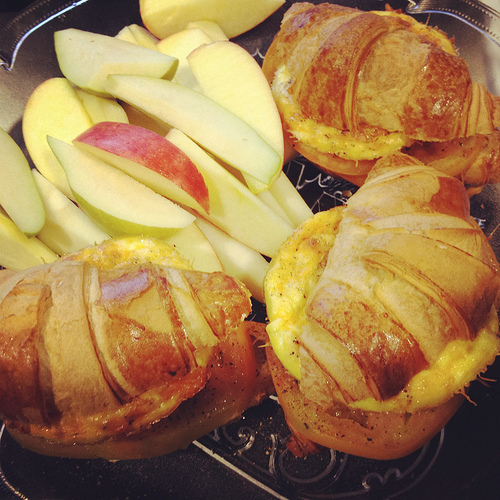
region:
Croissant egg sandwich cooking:
[264, 151, 499, 464]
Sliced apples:
[0, 1, 314, 303]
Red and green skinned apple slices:
[44, 122, 211, 237]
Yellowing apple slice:
[23, 75, 102, 202]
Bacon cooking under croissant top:
[0, 258, 252, 448]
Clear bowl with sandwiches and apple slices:
[0, 1, 499, 499]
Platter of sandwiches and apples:
[3, 3, 498, 498]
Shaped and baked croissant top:
[297, 153, 499, 409]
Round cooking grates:
[207, 148, 498, 498]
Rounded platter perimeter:
[2, 1, 498, 76]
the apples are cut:
[15, 27, 307, 294]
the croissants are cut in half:
[272, 145, 494, 455]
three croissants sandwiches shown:
[0, 5, 495, 468]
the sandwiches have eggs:
[276, 202, 499, 407]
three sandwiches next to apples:
[0, 0, 496, 499]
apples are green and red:
[0, 0, 319, 265]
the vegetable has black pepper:
[173, 327, 256, 423]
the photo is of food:
[8, 0, 495, 497]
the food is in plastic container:
[1, 0, 496, 493]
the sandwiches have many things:
[1, 6, 498, 456]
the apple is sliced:
[33, 28, 265, 203]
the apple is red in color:
[133, 134, 170, 159]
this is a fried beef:
[2, 266, 247, 429]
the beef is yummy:
[308, 173, 462, 452]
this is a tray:
[468, 6, 488, 53]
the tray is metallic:
[465, 7, 491, 52]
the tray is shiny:
[210, 434, 277, 499]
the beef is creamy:
[219, 348, 261, 401]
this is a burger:
[335, 409, 397, 452]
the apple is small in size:
[168, 84, 224, 136]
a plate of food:
[11, 7, 487, 493]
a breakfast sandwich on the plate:
[265, 135, 485, 475]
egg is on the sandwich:
[265, 202, 477, 369]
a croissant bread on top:
[254, 145, 476, 427]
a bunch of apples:
[15, 42, 280, 237]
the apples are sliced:
[3, 40, 263, 250]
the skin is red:
[65, 90, 230, 208]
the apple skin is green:
[30, 185, 191, 246]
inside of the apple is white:
[87, 57, 280, 195]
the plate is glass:
[2, 15, 489, 490]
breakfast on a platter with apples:
[22, 13, 488, 476]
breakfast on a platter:
[270, 153, 492, 455]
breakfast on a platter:
[1, 254, 280, 439]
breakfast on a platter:
[265, 8, 491, 183]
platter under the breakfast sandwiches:
[244, 441, 356, 497]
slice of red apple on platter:
[67, 105, 237, 205]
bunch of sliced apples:
[34, 35, 256, 202]